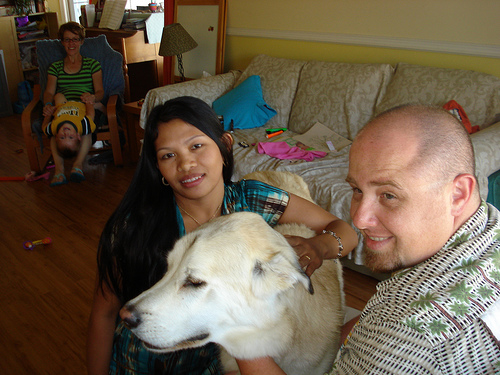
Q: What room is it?
A: It is a living room.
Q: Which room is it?
A: It is a living room.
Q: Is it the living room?
A: Yes, it is the living room.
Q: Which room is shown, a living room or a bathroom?
A: It is a living room.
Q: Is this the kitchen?
A: No, it is the living room.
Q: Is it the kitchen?
A: No, it is the living room.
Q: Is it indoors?
A: Yes, it is indoors.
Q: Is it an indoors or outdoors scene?
A: It is indoors.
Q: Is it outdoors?
A: No, it is indoors.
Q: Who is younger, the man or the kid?
A: The kid is younger than the man.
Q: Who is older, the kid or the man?
A: The man is older than the kid.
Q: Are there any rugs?
A: No, there are no rugs.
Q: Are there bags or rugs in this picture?
A: No, there are no rugs or bags.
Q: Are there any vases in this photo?
A: No, there are no vases.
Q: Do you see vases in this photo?
A: No, there are no vases.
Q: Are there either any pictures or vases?
A: No, there are no vases or pictures.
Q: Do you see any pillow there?
A: Yes, there is a pillow.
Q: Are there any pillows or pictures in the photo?
A: Yes, there is a pillow.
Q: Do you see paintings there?
A: No, there are no paintings.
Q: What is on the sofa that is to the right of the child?
A: The pillow is on the sofa.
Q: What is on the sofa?
A: The pillow is on the sofa.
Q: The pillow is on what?
A: The pillow is on the sofa.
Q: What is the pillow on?
A: The pillow is on the sofa.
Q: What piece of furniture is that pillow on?
A: The pillow is on the sofa.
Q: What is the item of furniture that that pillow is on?
A: The piece of furniture is a sofa.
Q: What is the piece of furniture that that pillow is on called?
A: The piece of furniture is a sofa.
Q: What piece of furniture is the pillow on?
A: The pillow is on the sofa.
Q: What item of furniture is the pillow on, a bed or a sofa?
A: The pillow is on a sofa.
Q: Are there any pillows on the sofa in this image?
A: Yes, there is a pillow on the sofa.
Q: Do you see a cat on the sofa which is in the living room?
A: No, there is a pillow on the sofa.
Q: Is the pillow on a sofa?
A: Yes, the pillow is on a sofa.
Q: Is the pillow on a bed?
A: No, the pillow is on a sofa.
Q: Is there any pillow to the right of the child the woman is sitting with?
A: Yes, there is a pillow to the right of the child.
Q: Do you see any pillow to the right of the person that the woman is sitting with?
A: Yes, there is a pillow to the right of the child.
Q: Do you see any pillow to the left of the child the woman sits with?
A: No, the pillow is to the right of the child.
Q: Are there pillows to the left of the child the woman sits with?
A: No, the pillow is to the right of the child.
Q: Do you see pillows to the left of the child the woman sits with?
A: No, the pillow is to the right of the child.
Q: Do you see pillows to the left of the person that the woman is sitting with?
A: No, the pillow is to the right of the child.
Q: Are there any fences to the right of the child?
A: No, there is a pillow to the right of the child.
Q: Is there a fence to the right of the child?
A: No, there is a pillow to the right of the child.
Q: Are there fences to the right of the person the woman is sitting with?
A: No, there is a pillow to the right of the child.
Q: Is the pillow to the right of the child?
A: Yes, the pillow is to the right of the child.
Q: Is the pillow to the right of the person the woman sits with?
A: Yes, the pillow is to the right of the child.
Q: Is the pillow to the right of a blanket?
A: No, the pillow is to the right of the child.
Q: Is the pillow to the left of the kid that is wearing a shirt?
A: No, the pillow is to the right of the kid.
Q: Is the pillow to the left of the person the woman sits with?
A: No, the pillow is to the right of the kid.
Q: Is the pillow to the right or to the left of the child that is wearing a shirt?
A: The pillow is to the right of the kid.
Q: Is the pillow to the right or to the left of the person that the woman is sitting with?
A: The pillow is to the right of the kid.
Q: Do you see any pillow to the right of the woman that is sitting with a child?
A: Yes, there is a pillow to the right of the woman.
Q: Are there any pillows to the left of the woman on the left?
A: No, the pillow is to the right of the woman.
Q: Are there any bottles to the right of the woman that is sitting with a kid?
A: No, there is a pillow to the right of the woman.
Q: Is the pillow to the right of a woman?
A: Yes, the pillow is to the right of a woman.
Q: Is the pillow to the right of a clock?
A: No, the pillow is to the right of a woman.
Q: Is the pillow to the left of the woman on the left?
A: No, the pillow is to the right of the woman.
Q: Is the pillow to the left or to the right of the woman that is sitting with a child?
A: The pillow is to the right of the woman.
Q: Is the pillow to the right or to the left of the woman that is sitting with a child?
A: The pillow is to the right of the woman.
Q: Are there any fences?
A: No, there are no fences.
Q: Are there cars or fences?
A: No, there are no fences or cars.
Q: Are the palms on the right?
A: Yes, the palms are on the right of the image.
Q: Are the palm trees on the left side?
A: No, the palm trees are on the right of the image.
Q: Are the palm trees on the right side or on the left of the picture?
A: The palm trees are on the right of the image.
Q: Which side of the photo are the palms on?
A: The palms are on the right of the image.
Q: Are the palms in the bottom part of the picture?
A: Yes, the palms are in the bottom of the image.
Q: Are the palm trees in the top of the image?
A: No, the palm trees are in the bottom of the image.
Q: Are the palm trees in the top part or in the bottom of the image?
A: The palm trees are in the bottom of the image.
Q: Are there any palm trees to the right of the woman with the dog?
A: Yes, there are palm trees to the right of the woman.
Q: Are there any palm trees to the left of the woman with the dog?
A: No, the palm trees are to the right of the woman.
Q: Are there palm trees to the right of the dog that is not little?
A: Yes, there are palm trees to the right of the dog.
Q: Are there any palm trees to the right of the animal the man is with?
A: Yes, there are palm trees to the right of the dog.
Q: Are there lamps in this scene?
A: Yes, there is a lamp.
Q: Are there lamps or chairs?
A: Yes, there is a lamp.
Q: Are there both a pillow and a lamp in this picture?
A: Yes, there are both a lamp and a pillow.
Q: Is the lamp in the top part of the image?
A: Yes, the lamp is in the top of the image.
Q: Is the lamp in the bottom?
A: No, the lamp is in the top of the image.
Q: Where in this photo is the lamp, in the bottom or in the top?
A: The lamp is in the top of the image.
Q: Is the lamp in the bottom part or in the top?
A: The lamp is in the top of the image.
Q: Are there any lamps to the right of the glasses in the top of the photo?
A: Yes, there is a lamp to the right of the glasses.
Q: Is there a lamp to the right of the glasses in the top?
A: Yes, there is a lamp to the right of the glasses.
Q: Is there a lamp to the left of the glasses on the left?
A: No, the lamp is to the right of the glasses.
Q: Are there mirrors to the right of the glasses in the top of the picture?
A: No, there is a lamp to the right of the glasses.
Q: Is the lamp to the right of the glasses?
A: Yes, the lamp is to the right of the glasses.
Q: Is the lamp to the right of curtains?
A: No, the lamp is to the right of the glasses.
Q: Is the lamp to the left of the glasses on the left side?
A: No, the lamp is to the right of the glasses.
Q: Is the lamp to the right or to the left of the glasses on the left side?
A: The lamp is to the right of the glasses.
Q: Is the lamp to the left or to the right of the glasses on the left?
A: The lamp is to the right of the glasses.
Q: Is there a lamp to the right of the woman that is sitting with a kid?
A: Yes, there is a lamp to the right of the woman.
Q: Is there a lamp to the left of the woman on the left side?
A: No, the lamp is to the right of the woman.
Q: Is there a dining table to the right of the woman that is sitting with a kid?
A: No, there is a lamp to the right of the woman.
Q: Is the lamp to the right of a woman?
A: Yes, the lamp is to the right of a woman.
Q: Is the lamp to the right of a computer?
A: No, the lamp is to the right of a woman.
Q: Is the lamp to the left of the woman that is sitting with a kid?
A: No, the lamp is to the right of the woman.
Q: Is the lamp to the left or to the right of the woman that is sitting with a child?
A: The lamp is to the right of the woman.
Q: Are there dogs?
A: Yes, there is a dog.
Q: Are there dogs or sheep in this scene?
A: Yes, there is a dog.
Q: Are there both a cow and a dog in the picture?
A: No, there is a dog but no cows.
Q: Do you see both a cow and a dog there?
A: No, there is a dog but no cows.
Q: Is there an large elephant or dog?
A: Yes, there is a large dog.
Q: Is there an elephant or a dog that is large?
A: Yes, the dog is large.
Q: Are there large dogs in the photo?
A: Yes, there is a large dog.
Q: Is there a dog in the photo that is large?
A: Yes, there is a dog that is large.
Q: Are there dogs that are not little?
A: Yes, there is a large dog.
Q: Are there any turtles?
A: No, there are no turtles.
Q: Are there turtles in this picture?
A: No, there are no turtles.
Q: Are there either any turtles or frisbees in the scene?
A: No, there are no turtles or frisbees.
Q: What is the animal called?
A: The animal is a dog.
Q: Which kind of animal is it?
A: The animal is a dog.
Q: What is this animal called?
A: This is a dog.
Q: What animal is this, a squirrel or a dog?
A: This is a dog.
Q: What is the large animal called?
A: The animal is a dog.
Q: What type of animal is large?
A: The animal is a dog.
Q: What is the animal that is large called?
A: The animal is a dog.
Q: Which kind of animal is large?
A: The animal is a dog.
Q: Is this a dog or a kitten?
A: This is a dog.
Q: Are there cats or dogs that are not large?
A: No, there is a dog but it is large.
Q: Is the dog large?
A: Yes, the dog is large.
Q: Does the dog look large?
A: Yes, the dog is large.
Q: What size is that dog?
A: The dog is large.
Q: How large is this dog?
A: The dog is large.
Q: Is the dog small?
A: No, the dog is large.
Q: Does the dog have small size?
A: No, the dog is large.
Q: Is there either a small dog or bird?
A: No, there is a dog but it is large.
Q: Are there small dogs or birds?
A: No, there is a dog but it is large.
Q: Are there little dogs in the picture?
A: No, there is a dog but it is large.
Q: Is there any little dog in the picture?
A: No, there is a dog but it is large.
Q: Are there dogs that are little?
A: No, there is a dog but it is large.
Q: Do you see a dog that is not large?
A: No, there is a dog but it is large.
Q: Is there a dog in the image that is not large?
A: No, there is a dog but it is large.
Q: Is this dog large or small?
A: The dog is large.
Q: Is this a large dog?
A: Yes, this is a large dog.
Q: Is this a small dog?
A: No, this is a large dog.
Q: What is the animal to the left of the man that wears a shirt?
A: The animal is a dog.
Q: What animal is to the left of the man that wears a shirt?
A: The animal is a dog.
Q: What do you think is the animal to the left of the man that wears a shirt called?
A: The animal is a dog.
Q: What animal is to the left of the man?
A: The animal is a dog.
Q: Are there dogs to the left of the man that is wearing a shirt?
A: Yes, there is a dog to the left of the man.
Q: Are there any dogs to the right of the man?
A: No, the dog is to the left of the man.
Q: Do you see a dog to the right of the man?
A: No, the dog is to the left of the man.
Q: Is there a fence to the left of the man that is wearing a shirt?
A: No, there is a dog to the left of the man.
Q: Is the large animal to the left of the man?
A: Yes, the dog is to the left of the man.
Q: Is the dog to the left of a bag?
A: No, the dog is to the left of the man.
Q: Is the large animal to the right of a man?
A: No, the dog is to the left of a man.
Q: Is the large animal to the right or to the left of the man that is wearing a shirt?
A: The dog is to the left of the man.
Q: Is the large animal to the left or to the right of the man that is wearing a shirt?
A: The dog is to the left of the man.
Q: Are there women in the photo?
A: Yes, there is a woman.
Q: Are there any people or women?
A: Yes, there is a woman.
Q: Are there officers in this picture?
A: No, there are no officers.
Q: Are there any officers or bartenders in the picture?
A: No, there are no officers or bartenders.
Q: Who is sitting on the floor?
A: The woman is sitting on the floor.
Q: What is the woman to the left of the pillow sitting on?
A: The woman is sitting on the floor.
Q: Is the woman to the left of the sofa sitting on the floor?
A: Yes, the woman is sitting on the floor.